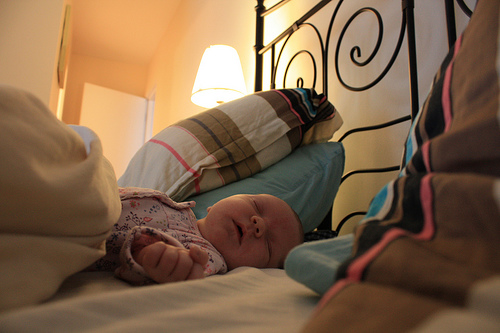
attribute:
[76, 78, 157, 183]
door — white, open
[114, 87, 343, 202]
pillow — colorful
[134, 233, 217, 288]
hand — closed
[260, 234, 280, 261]
eye — closed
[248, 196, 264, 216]
eye — closed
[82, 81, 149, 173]
door — open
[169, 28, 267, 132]
lamp — on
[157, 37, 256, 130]
light — on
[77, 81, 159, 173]
door — white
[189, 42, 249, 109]
lamp — turned on